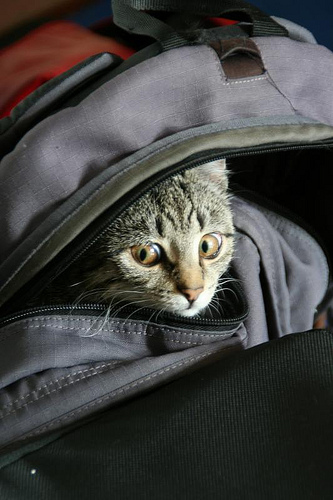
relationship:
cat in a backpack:
[113, 175, 225, 305] [12, 30, 330, 400]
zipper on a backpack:
[8, 241, 118, 336] [12, 30, 330, 400]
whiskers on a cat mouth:
[73, 266, 176, 319] [167, 295, 207, 327]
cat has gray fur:
[113, 175, 225, 305] [171, 187, 205, 203]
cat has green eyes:
[113, 175, 225, 305] [195, 235, 218, 258]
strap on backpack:
[108, 2, 279, 38] [12, 30, 330, 400]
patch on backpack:
[18, 30, 138, 73] [12, 30, 330, 400]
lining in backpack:
[254, 177, 331, 300] [12, 30, 330, 400]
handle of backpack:
[108, 2, 279, 38] [12, 30, 330, 400]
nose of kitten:
[179, 286, 204, 304] [113, 175, 225, 305]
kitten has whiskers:
[113, 175, 225, 305] [73, 266, 176, 319]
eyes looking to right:
[124, 234, 224, 268] [48, 234, 67, 276]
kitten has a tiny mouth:
[113, 175, 225, 305] [167, 295, 207, 327]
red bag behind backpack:
[6, 11, 149, 82] [12, 30, 330, 400]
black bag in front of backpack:
[65, 376, 330, 497] [12, 30, 330, 400]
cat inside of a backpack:
[113, 175, 225, 305] [12, 30, 330, 400]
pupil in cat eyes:
[202, 237, 210, 258] [124, 234, 224, 268]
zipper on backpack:
[8, 241, 118, 336] [12, 30, 330, 400]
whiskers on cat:
[73, 266, 176, 319] [113, 175, 225, 305]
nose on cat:
[179, 286, 204, 304] [113, 175, 225, 305]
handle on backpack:
[108, 2, 279, 38] [12, 30, 330, 400]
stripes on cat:
[159, 191, 207, 215] [113, 175, 225, 305]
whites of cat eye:
[215, 229, 225, 247] [198, 233, 225, 262]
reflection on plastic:
[23, 25, 106, 72] [67, 40, 79, 45]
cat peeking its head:
[113, 175, 225, 305] [156, 199, 209, 225]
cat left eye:
[113, 175, 225, 305] [126, 236, 158, 265]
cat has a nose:
[113, 175, 225, 305] [179, 286, 204, 304]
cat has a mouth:
[113, 175, 225, 305] [167, 295, 207, 327]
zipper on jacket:
[8, 241, 118, 336] [237, 189, 324, 285]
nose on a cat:
[179, 286, 204, 304] [113, 175, 225, 305]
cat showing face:
[113, 175, 225, 305] [139, 231, 236, 305]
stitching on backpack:
[211, 57, 273, 89] [12, 30, 330, 400]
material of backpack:
[101, 76, 246, 136] [12, 30, 330, 400]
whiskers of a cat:
[73, 266, 176, 319] [113, 175, 225, 305]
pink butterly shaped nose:
[180, 288, 202, 298] [179, 286, 204, 304]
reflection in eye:
[23, 25, 106, 72] [198, 233, 225, 262]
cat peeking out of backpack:
[113, 175, 225, 305] [12, 30, 330, 400]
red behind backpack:
[25, 28, 101, 74] [12, 30, 330, 400]